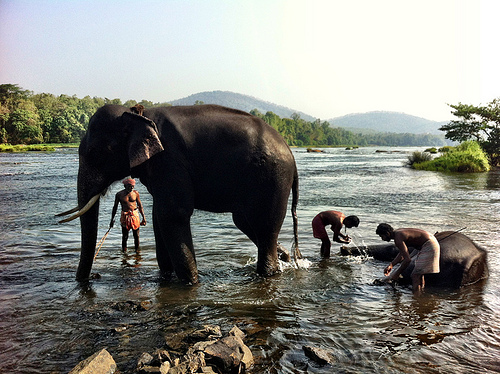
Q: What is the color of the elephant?
A: Black.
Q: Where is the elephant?
A: In the water.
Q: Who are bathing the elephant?
A: People.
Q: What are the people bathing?
A: Elephants.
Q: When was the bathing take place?
A: Daytime.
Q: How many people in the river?
A: Three.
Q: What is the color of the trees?
A: Green.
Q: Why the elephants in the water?
A: Bathing.